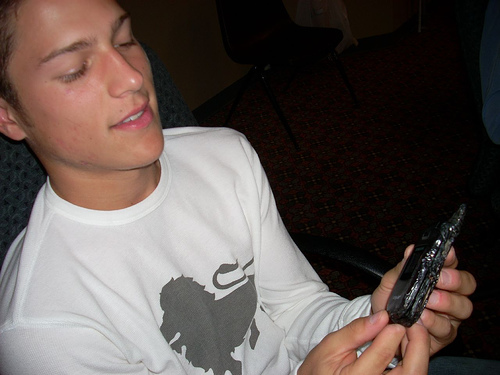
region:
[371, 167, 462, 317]
melted phone in boy's hand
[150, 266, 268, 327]
lion on boy's white shirt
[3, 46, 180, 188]
the boy's face looking down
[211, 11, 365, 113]
black chair in dark corner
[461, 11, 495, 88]
a person's arm in the corner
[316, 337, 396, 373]
the boy's hand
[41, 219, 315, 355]
the boy's white long sleeved t-shirt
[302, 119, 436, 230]
the dark colorful carpet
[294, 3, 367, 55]
white mystery item next to chair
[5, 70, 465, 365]
boy staring down at the melted phone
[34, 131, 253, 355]
white shirt on boy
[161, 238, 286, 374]
gray lion on shirt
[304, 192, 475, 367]
boy's hands holding something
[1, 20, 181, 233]
face of the boy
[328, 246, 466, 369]
hands of the boy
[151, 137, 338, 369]
long sleeve shirt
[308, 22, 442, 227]
patterned floor on ground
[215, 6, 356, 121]
chair on the ground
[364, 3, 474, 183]
red and green floor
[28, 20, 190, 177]
boy looking down at something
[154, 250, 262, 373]
The gray design on the guy's shirt.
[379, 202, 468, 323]
The cell phone in the guy's hands.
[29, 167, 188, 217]
The collar of the white shirt the guy is wearing.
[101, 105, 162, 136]
The guy's mouth and teeth.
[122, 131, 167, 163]
The chin of the guy in the white shirt.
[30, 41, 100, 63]
The guy's left eyebrow.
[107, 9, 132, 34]
The right eyebrow of the guy.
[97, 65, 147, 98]
The guy's nose and nostrils.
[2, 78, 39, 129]
The side burn of the guy.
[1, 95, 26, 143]
The left ear of the guy.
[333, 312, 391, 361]
the finger of a person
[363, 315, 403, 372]
the finger of a person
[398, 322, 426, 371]
the finger of a person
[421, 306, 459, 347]
the finger of a person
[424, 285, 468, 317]
the finger of a person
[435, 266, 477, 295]
the finger of a person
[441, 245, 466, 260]
the finger of a person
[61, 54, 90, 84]
the eye of a person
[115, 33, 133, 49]
the eye of a person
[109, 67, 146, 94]
the nose of a person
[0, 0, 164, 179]
The man's face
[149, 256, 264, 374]
The lion on the man's shirt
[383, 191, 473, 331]
The burnt phone in the man's hands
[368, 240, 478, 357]
The man's left hand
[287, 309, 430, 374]
The man's right hand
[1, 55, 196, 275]
The back of the chair the man is on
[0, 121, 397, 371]
The man's white shirt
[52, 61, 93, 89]
The right eye of the man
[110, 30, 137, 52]
The left eye of the man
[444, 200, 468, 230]
The antenna of the phone